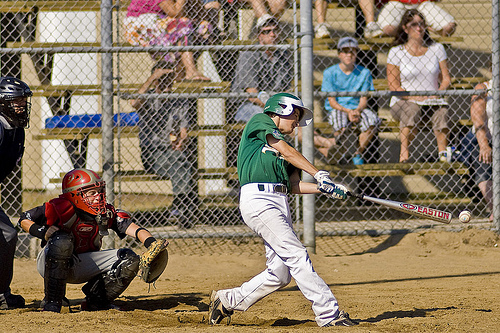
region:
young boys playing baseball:
[5, 77, 450, 325]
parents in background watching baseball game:
[5, 1, 492, 90]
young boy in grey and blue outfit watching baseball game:
[324, 38, 375, 163]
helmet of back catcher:
[62, 169, 107, 216]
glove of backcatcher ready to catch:
[142, 239, 169, 282]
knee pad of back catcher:
[115, 246, 140, 282]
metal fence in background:
[105, 0, 237, 180]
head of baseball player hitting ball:
[267, 93, 312, 130]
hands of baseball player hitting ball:
[317, 178, 348, 200]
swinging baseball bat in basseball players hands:
[352, 190, 454, 223]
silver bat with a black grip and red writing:
[347, 188, 454, 223]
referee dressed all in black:
[0, 75, 35, 312]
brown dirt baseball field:
[1, 228, 499, 330]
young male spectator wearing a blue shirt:
[319, 35, 379, 167]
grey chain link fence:
[0, 0, 499, 259]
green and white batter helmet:
[264, 92, 314, 129]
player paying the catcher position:
[17, 166, 170, 311]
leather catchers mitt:
[139, 236, 170, 285]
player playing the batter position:
[210, 90, 350, 328]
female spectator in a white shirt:
[386, 7, 456, 174]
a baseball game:
[5, 10, 495, 313]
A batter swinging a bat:
[223, 65, 472, 331]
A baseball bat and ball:
[325, 170, 480, 242]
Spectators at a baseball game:
[140, 6, 495, 105]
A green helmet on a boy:
[255, 84, 311, 134]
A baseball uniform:
[228, 89, 335, 331]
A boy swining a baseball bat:
[230, 73, 450, 320]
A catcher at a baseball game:
[19, 147, 183, 316]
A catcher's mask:
[60, 164, 113, 226]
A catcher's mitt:
[133, 228, 180, 285]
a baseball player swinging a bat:
[213, 92, 454, 324]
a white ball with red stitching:
[459, 210, 471, 222]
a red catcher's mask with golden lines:
[61, 169, 109, 217]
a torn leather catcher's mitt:
[135, 235, 172, 292]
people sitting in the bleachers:
[323, 75, 498, 173]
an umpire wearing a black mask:
[1, 78, 33, 130]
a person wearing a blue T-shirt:
[323, 75, 373, 110]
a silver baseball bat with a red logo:
[364, 193, 452, 225]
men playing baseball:
[1, 76, 474, 331]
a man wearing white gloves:
[313, 172, 347, 202]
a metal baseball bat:
[311, 168, 453, 238]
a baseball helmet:
[261, 88, 321, 130]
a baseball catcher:
[25, 157, 175, 316]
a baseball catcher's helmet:
[56, 164, 121, 221]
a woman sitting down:
[381, 2, 457, 184]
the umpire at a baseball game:
[6, 73, 45, 315]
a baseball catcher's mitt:
[128, 230, 190, 295]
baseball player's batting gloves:
[310, 166, 353, 208]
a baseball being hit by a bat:
[354, 182, 488, 242]